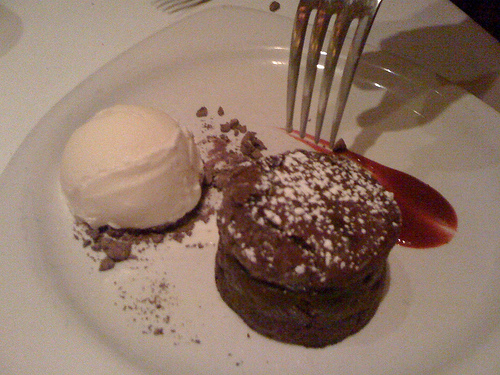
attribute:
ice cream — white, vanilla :
[57, 100, 202, 231]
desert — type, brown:
[207, 150, 405, 351]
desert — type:
[55, 95, 217, 247]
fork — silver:
[285, 8, 374, 140]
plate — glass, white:
[0, 7, 499, 374]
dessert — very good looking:
[60, 102, 457, 367]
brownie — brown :
[250, 217, 367, 297]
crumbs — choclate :
[185, 93, 265, 163]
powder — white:
[263, 149, 388, 240]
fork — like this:
[280, 2, 383, 148]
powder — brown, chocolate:
[187, 100, 259, 163]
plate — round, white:
[0, 28, 467, 371]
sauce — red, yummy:
[321, 138, 473, 263]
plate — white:
[24, 14, 491, 361]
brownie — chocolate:
[197, 152, 405, 343]